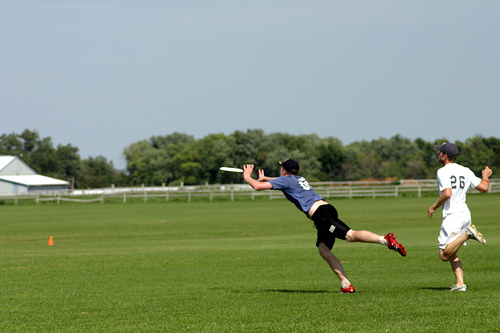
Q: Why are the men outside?
A: Playing frisbee.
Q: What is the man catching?
A: A frisbee.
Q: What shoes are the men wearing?
A: Cleats.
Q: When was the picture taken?
A: In the daytime.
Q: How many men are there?
A: Two.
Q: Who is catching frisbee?
A: Man in blue shirt.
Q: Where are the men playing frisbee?
A: On a field.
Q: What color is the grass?
A: Green.